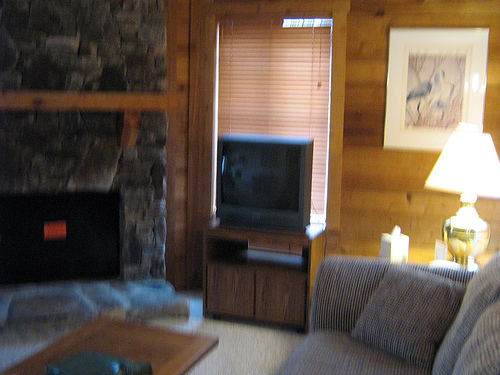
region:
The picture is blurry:
[16, 12, 494, 367]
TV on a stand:
[198, 104, 333, 231]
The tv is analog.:
[205, 127, 323, 241]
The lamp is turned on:
[420, 103, 496, 298]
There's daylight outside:
[194, 0, 350, 233]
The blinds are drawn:
[202, 7, 340, 231]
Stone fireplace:
[4, 4, 204, 325]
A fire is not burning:
[0, 182, 142, 286]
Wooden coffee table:
[11, 298, 230, 367]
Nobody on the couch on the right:
[255, 248, 497, 373]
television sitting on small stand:
[210, 133, 313, 235]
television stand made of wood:
[207, 222, 319, 328]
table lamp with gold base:
[424, 125, 496, 272]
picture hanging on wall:
[381, 26, 483, 146]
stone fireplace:
[2, 3, 179, 323]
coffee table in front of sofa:
[7, 311, 221, 371]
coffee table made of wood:
[5, 312, 215, 374]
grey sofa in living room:
[280, 253, 496, 374]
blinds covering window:
[215, 20, 324, 218]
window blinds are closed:
[216, 22, 327, 223]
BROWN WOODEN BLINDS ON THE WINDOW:
[199, 3, 366, 190]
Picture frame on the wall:
[371, 21, 498, 169]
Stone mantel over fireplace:
[4, 5, 168, 236]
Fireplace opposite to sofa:
[1, 177, 158, 296]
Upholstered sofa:
[297, 241, 485, 373]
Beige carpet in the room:
[215, 323, 285, 367]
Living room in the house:
[4, 8, 496, 323]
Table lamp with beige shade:
[423, 112, 498, 252]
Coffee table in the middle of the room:
[14, 282, 207, 374]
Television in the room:
[217, 123, 324, 250]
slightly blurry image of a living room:
[4, 5, 492, 374]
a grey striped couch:
[301, 258, 498, 373]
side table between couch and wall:
[336, 155, 498, 303]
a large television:
[213, 132, 314, 234]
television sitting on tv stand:
[207, 135, 319, 328]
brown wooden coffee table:
[16, 310, 221, 374]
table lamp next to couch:
[426, 126, 499, 339]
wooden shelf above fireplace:
[2, 79, 167, 222]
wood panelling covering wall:
[336, 7, 401, 227]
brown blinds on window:
[202, 18, 329, 237]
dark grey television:
[198, 123, 319, 241]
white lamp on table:
[424, 128, 485, 255]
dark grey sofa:
[298, 261, 473, 374]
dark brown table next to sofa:
[12, 312, 195, 365]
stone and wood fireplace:
[16, 1, 191, 291]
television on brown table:
[188, 213, 319, 333]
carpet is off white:
[157, 295, 290, 370]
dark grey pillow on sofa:
[362, 262, 443, 357]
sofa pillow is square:
[341, 256, 463, 371]